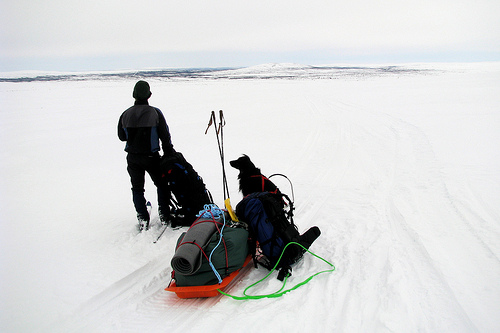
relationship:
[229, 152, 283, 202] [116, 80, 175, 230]
dog near man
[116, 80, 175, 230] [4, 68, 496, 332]
man on field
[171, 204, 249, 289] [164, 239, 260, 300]
backpack over sled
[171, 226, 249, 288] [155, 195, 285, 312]
bags on sled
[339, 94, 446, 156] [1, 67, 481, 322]
snow covering ground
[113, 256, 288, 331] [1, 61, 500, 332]
tracks in snow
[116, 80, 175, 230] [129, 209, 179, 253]
man on skis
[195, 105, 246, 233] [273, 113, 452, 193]
poles stuck in snow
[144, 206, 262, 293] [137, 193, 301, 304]
bags on sled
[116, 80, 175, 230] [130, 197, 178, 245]
man on skis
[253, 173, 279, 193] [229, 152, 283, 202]
strap on dog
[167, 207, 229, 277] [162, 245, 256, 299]
sleeping bag on sled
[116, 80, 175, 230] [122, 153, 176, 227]
man wearing pants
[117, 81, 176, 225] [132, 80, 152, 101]
man wearing hat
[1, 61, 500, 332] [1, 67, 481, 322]
snow on ground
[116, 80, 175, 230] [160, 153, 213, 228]
man holds backpack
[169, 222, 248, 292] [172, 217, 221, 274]
backpack with a mat